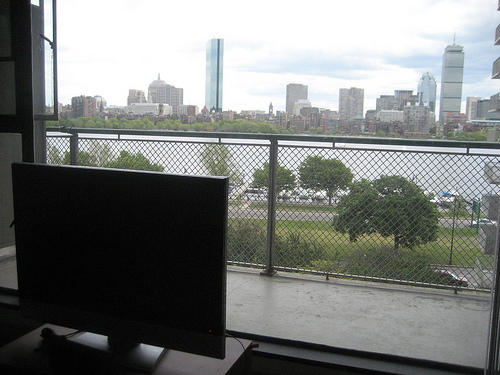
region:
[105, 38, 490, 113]
the houses are tall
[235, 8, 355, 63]
the sky is cloudy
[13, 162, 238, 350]
the tv is black in colour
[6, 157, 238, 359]
the tv is off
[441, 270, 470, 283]
the car is black in colour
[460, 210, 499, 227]
the car is white in colour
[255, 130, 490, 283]
the fence is wire meshed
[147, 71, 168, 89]
the house is dome shaped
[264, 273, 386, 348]
the floor is grey in colour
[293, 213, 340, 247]
the grass is green in colour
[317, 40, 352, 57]
this is the sky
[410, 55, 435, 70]
the sky is blue in color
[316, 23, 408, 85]
the sky has clouds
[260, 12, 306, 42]
the clouds are white in color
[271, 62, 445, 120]
these are some buildings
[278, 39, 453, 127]
the buildings are tall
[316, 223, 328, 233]
this is the grass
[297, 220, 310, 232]
the grass is green in color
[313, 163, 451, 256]
this is a tree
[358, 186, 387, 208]
the leaves are green in color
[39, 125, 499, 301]
chain link fence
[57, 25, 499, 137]
skyline across the water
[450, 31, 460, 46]
tall pole on the top of the building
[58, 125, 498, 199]
calm body of water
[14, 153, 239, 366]
computer monitor that is turned off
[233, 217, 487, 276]
green grass on the ground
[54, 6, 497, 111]
thick clouds in the sky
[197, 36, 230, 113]
tall and narrow building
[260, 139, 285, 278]
pole holding up the chain link fence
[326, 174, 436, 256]
thick dark green tree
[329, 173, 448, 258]
thick gree tree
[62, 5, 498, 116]
thick clouds covering the sky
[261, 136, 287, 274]
pole that is supporting the fence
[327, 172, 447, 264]
tree growing out of the grass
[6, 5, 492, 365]
window looking out at park, river and city skyline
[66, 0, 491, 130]
bright sky with patches of clouds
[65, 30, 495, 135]
a couple of tall buildings standing out from shorter buildings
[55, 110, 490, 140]
trees lining edge of far side of river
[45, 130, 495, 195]
light grey water of river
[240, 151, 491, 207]
small boats at the edge of the river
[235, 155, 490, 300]
cars on roads between lawns and trees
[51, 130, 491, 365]
metal railing on front of terrace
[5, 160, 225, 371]
dark panel of television screen by window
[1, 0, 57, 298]
narrow windows open to side